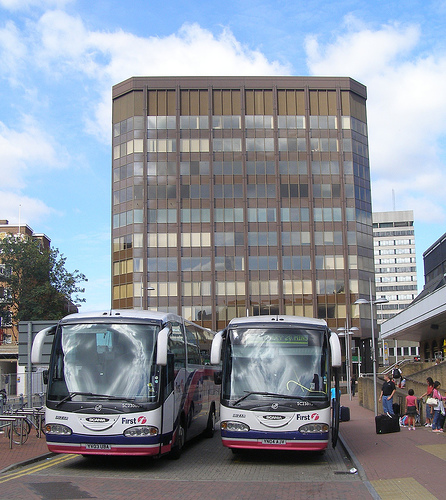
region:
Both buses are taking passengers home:
[18, 158, 442, 491]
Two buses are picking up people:
[4, 215, 439, 496]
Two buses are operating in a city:
[2, 143, 438, 491]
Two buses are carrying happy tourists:
[2, 183, 438, 494]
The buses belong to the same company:
[2, 204, 438, 495]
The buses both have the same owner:
[0, 232, 443, 489]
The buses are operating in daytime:
[0, 210, 430, 492]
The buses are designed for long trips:
[5, 213, 435, 495]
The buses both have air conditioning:
[9, 204, 440, 476]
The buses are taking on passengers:
[15, 216, 431, 484]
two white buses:
[37, 307, 347, 470]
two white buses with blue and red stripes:
[31, 308, 354, 474]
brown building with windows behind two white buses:
[19, 73, 382, 466]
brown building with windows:
[109, 76, 379, 396]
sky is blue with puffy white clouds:
[1, 0, 445, 305]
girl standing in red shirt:
[402, 385, 419, 432]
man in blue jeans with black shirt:
[375, 372, 395, 415]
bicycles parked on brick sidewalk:
[0, 401, 45, 474]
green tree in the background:
[0, 232, 89, 324]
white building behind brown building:
[372, 185, 417, 326]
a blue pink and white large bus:
[28, 309, 219, 456]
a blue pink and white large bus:
[210, 315, 345, 457]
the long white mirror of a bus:
[29, 328, 57, 357]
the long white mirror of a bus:
[155, 323, 172, 364]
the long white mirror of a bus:
[208, 328, 224, 360]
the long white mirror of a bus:
[327, 328, 342, 367]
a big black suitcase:
[333, 404, 349, 421]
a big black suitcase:
[374, 411, 398, 431]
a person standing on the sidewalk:
[381, 371, 395, 416]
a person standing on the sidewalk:
[424, 375, 436, 424]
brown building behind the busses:
[111, 75, 376, 324]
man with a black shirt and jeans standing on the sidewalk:
[376, 374, 402, 433]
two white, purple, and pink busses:
[56, 311, 327, 456]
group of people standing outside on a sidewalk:
[377, 376, 443, 437]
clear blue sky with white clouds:
[14, 7, 409, 70]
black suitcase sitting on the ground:
[374, 411, 400, 432]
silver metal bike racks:
[6, 408, 39, 446]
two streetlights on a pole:
[355, 277, 387, 403]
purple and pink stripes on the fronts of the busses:
[44, 429, 326, 453]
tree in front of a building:
[8, 238, 81, 313]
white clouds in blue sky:
[18, 15, 77, 68]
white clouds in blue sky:
[25, 113, 59, 150]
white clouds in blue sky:
[36, 105, 98, 168]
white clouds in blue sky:
[43, 18, 103, 59]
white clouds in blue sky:
[120, 6, 188, 59]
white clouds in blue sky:
[216, 13, 265, 55]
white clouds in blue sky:
[386, 29, 411, 82]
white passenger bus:
[204, 298, 347, 457]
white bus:
[14, 316, 219, 471]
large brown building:
[118, 72, 378, 312]